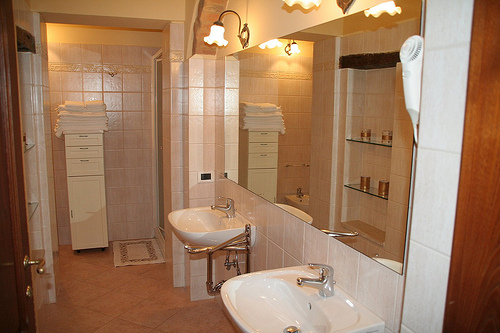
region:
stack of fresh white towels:
[47, 91, 109, 143]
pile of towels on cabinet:
[54, 94, 121, 256]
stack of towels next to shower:
[45, 93, 116, 141]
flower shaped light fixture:
[200, 5, 251, 52]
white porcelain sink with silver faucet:
[170, 183, 250, 258]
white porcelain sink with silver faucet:
[214, 238, 382, 329]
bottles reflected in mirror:
[344, 117, 394, 204]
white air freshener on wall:
[390, 35, 442, 143]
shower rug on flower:
[108, 223, 169, 271]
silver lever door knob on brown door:
[11, 245, 52, 276]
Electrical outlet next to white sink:
[196, 168, 216, 183]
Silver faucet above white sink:
[207, 194, 236, 219]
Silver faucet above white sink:
[293, 258, 337, 298]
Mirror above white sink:
[210, 0, 423, 280]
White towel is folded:
[64, 95, 84, 111]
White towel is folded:
[85, 98, 109, 110]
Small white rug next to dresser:
[112, 238, 165, 269]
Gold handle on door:
[21, 255, 47, 276]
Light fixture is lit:
[200, 7, 251, 49]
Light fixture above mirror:
[202, 9, 252, 48]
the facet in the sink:
[209, 188, 236, 220]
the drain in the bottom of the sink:
[283, 319, 307, 331]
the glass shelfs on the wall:
[335, 127, 400, 203]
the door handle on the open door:
[22, 252, 49, 279]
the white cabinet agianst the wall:
[61, 133, 113, 250]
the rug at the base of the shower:
[112, 236, 166, 273]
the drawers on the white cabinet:
[65, 131, 105, 176]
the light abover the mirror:
[204, 3, 251, 53]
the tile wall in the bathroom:
[117, 49, 155, 234]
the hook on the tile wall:
[108, 66, 120, 80]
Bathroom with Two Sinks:
[2, 0, 498, 328]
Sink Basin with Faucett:
[167, 196, 254, 250]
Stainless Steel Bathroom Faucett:
[293, 257, 343, 300]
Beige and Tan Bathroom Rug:
[111, 234, 163, 269]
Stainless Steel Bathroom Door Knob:
[21, 248, 48, 276]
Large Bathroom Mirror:
[221, 46, 416, 210]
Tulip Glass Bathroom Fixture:
[204, 7, 253, 51]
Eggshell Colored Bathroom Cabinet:
[55, 93, 114, 255]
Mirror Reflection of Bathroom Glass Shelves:
[331, 47, 401, 244]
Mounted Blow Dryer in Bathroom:
[396, 27, 423, 144]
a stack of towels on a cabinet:
[57, 87, 112, 142]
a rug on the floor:
[104, 231, 161, 279]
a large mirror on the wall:
[199, 0, 369, 192]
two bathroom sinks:
[167, 192, 358, 331]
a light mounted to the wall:
[199, 4, 251, 67]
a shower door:
[151, 47, 162, 239]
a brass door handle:
[17, 243, 51, 292]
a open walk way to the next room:
[36, 2, 181, 287]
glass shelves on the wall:
[340, 67, 403, 237]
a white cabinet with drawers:
[52, 129, 109, 276]